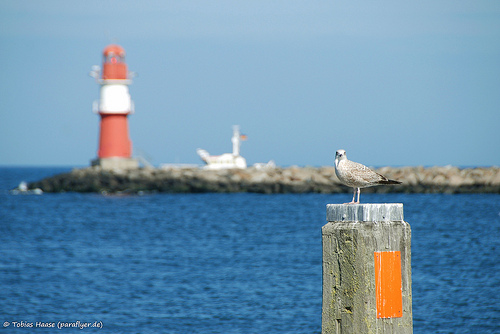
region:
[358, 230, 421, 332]
an orange sign on a post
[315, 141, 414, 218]
a small white seagull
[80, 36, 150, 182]
a red and white lighthouse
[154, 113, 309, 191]
a boat in the background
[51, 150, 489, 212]
a large amount of rocks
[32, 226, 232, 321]
small waves in the water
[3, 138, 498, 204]
a man made peninsula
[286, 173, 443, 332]
a square concrete post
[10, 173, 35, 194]
a small white cap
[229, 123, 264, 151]
a flag in the distance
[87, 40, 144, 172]
Lighthouse is white and orange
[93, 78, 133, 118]
White color in center of lighthouse.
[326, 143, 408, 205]
Seabird stand in a pole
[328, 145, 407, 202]
Seabird beak is black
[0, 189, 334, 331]
Water is blue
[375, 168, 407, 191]
Tal of bird is black.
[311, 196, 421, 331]
Pole is cement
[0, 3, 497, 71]
Sky is blue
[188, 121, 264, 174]
Ship travels in the ocean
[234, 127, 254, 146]
Flag is flying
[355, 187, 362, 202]
a tiny bird's leg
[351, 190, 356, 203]
a tiny bird's leg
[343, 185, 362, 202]
a tiny bird's legs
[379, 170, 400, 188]
a tiny bird's black tail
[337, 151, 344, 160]
a tiny bird's beak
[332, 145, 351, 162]
a tiny bird's leg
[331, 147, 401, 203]
a tiny bird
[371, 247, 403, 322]
an orange painting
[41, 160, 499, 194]
an island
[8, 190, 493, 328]
a body of blue water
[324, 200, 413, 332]
a concrete pole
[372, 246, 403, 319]
an orange paint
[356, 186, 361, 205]
a tiny bird's leg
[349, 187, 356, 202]
a tiny bird's leg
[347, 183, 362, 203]
a tiny bird's leg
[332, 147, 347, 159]
a tiny bird's head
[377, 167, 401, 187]
a tiny bird's tail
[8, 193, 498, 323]
blue water in an ocean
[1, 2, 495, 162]
a clear sky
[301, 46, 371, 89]
part of a sky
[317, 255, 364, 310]
part of a stone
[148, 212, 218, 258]
part of a water body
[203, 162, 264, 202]
part of a lagoon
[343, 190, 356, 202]
legs of a bird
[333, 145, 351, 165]
face of a bird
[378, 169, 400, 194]
tail wing of a bird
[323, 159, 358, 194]
chest of a bird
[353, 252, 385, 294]
part of an orange board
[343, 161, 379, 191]
part of a wing